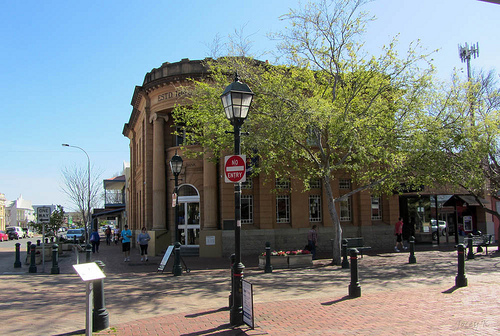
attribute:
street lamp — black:
[215, 64, 249, 327]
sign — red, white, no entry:
[221, 151, 249, 183]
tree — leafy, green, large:
[169, 0, 499, 265]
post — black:
[348, 247, 364, 298]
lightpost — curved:
[56, 142, 93, 253]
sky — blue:
[0, 1, 499, 204]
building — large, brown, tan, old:
[122, 56, 500, 263]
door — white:
[175, 200, 202, 248]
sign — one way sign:
[35, 205, 53, 224]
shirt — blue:
[119, 229, 134, 245]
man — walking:
[391, 216, 409, 255]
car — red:
[0, 230, 9, 242]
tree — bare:
[60, 159, 104, 256]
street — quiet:
[0, 233, 51, 272]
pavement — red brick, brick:
[59, 277, 499, 335]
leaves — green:
[168, 1, 499, 206]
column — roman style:
[149, 112, 171, 234]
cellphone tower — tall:
[455, 38, 482, 130]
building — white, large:
[4, 192, 38, 231]